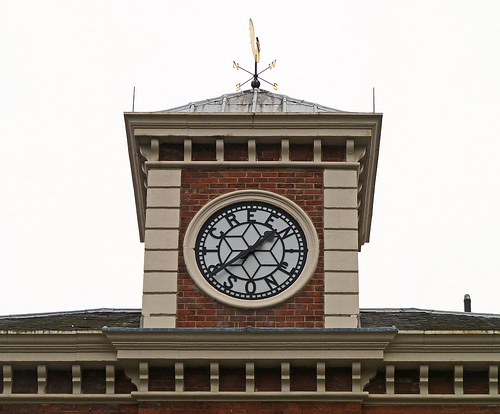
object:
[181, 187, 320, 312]
clock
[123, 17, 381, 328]
tower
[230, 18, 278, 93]
weather vane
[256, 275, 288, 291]
letter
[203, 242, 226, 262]
letter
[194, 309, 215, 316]
bricks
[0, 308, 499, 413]
building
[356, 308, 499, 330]
roof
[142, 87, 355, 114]
pyramid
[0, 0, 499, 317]
sky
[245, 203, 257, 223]
letter e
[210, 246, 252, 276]
clock hands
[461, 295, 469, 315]
exhaust vent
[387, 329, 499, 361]
decorative accent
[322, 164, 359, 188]
shingles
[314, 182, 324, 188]
part